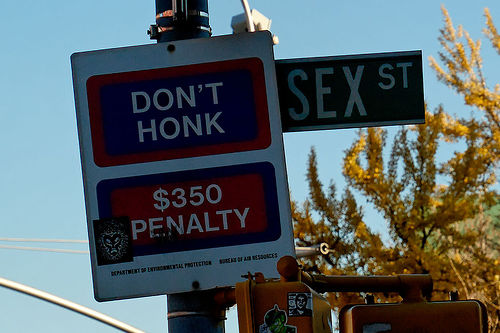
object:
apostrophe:
[198, 84, 203, 93]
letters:
[132, 82, 229, 142]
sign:
[68, 30, 296, 305]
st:
[378, 62, 413, 90]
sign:
[276, 49, 421, 135]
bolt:
[191, 280, 201, 289]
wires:
[0, 237, 90, 257]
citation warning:
[68, 29, 298, 304]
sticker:
[286, 292, 310, 317]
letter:
[287, 69, 310, 121]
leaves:
[284, 0, 500, 333]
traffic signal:
[234, 253, 480, 333]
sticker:
[93, 218, 136, 267]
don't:
[132, 76, 223, 114]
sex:
[290, 64, 369, 121]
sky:
[0, 0, 499, 333]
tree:
[288, 0, 500, 333]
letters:
[131, 207, 251, 242]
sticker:
[257, 303, 299, 333]